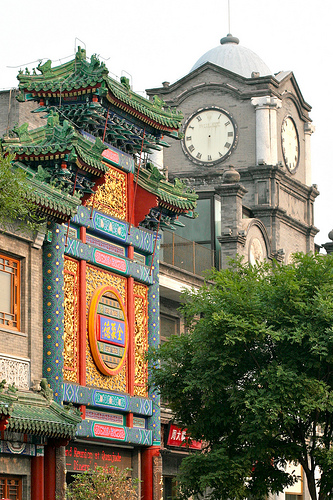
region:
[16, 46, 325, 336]
Asian buildings and clock tower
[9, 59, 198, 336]
decorative Asian building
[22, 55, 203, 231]
the roofing is green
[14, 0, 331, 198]
the sky is cloudy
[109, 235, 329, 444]
a huge tree in the foreground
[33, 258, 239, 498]
Asian buildings on a busy street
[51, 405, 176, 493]
neon Asian signs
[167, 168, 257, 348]
a section of the clock tower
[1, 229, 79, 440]
a window over a roof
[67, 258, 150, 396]
a colorful restaurant signage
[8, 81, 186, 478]
Chinese pagoda type building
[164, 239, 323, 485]
beautiful green trees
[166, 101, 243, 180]
old clock with Roman numeral I on it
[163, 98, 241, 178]
old clock with Roman numeral II on it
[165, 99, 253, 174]
old clock with Roman numeral III on it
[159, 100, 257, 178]
old clock with Roman numeral IV on it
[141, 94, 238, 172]
old clock with Roman numeral V on it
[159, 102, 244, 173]
old clock with Roman numeral VI on it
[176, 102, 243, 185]
old clock with Roman numeral VII on it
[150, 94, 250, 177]
old clock with Roman numeral VIII on it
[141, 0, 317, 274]
two clocks on a tall tower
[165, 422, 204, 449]
asian print on a red sign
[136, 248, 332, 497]
large green tree across from some buildings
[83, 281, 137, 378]
asian text orange colorful circular design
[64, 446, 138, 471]
red text on a black sign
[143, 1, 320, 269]
tall gray tower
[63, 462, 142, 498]
small green tree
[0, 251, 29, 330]
brownish frame on a window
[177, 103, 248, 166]
roman numerals on a clock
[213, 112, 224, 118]
roman numeral one on a clock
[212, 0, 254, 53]
pole on top of the clock tower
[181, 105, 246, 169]
the hands are missing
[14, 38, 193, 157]
ornate Chinese style architecture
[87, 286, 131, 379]
circular sign in Chinese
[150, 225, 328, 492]
leafy green tree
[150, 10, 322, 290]
a grey stone clock tower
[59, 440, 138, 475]
a sign with Western characters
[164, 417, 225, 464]
red and white rectangular sign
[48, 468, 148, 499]
a small tree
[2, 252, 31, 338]
window with opaque glass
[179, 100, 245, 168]
A clock on the tower.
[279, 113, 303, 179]
another clock on the side.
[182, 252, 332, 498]
A tree in the front.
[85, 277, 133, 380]
An asian building sign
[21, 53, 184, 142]
A green colored roof.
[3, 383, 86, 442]
An asian themed roof.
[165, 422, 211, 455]
A red sign in chinese.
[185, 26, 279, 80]
The dome of the tower.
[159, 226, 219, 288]
A fence on the balcony.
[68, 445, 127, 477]
A sign with red letters.